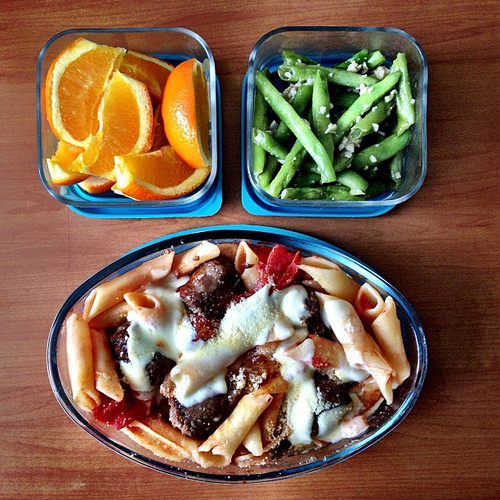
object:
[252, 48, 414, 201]
beans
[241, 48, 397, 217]
lid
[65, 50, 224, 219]
lid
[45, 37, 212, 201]
orange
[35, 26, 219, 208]
container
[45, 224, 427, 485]
bowl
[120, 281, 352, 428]
white sauce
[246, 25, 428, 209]
bowl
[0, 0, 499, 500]
table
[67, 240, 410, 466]
main dish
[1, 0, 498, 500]
wood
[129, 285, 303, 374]
cheese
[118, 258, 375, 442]
sauce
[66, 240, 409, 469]
pasta